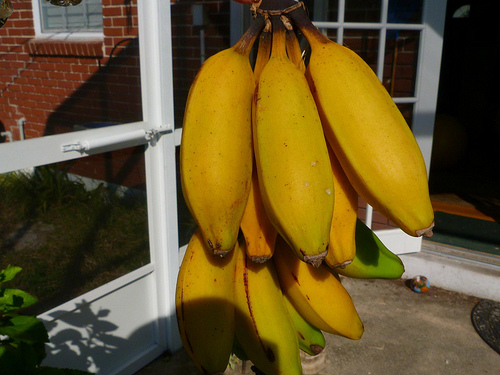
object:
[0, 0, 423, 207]
brick wall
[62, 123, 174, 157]
spring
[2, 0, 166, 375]
door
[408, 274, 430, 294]
toy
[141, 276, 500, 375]
ground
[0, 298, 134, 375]
shadow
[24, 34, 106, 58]
brick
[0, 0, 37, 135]
brick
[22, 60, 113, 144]
brick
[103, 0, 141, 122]
brick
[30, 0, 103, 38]
window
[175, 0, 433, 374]
bananas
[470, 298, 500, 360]
rug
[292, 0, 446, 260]
door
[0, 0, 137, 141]
casing